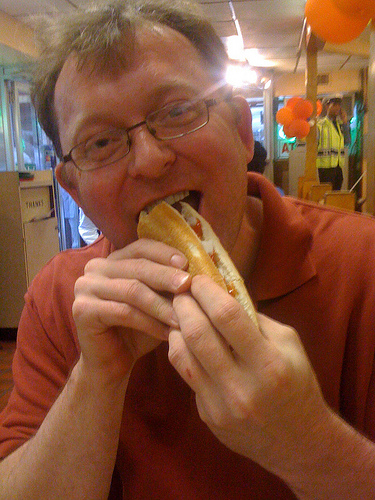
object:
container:
[0, 167, 63, 327]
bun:
[138, 199, 258, 330]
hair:
[23, 0, 243, 212]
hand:
[162, 267, 336, 468]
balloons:
[291, 118, 313, 143]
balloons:
[302, 3, 373, 45]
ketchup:
[187, 216, 202, 237]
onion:
[202, 238, 213, 255]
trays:
[16, 170, 35, 182]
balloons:
[269, 101, 293, 127]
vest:
[313, 117, 347, 170]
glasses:
[39, 92, 231, 171]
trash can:
[0, 169, 59, 342]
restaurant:
[0, 1, 372, 500]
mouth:
[126, 172, 217, 235]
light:
[226, 30, 278, 86]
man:
[0, 0, 375, 498]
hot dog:
[134, 189, 263, 354]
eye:
[154, 98, 201, 129]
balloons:
[288, 95, 312, 113]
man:
[316, 96, 349, 190]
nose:
[127, 125, 175, 179]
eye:
[76, 122, 135, 168]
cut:
[182, 364, 194, 381]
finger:
[163, 331, 210, 393]